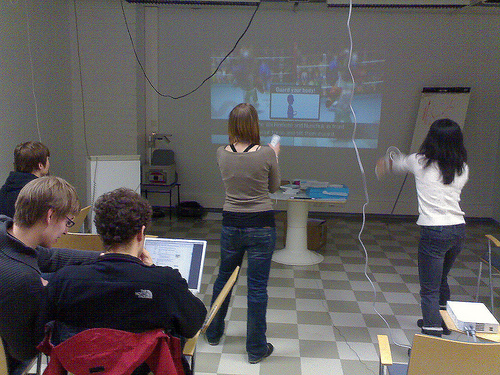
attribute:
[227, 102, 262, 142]
hair — brown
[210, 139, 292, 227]
shirt — grey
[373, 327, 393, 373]
wooden arm — wooden 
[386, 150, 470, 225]
shirt — white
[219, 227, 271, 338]
jeans — blue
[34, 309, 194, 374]
coat — red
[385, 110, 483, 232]
shirt — white 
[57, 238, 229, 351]
jacket — red, black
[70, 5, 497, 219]
wall — white 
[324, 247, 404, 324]
floor — grey, white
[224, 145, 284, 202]
sweater — brown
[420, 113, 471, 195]
hair — long , dark 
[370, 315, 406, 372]
arm — brown 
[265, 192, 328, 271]
base — white 